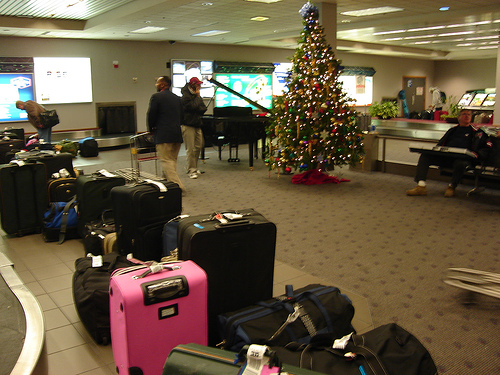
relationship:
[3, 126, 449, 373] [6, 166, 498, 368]
luggage on ground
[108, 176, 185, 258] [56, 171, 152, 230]
bag next to luggage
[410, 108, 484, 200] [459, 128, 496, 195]
man sitting on bench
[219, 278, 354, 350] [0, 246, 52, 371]
bag next to carousel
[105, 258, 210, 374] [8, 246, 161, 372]
bag on ground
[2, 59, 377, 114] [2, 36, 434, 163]
bill boards on wall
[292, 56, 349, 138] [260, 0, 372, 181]
ornaments on tree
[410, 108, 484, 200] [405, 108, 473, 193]
man sitting down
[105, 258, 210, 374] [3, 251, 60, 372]
bag next to carousel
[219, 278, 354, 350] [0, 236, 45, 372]
bag next to carousel